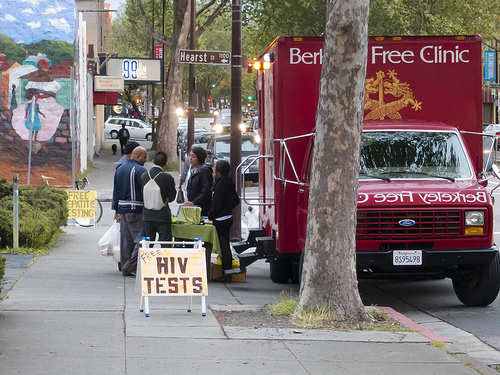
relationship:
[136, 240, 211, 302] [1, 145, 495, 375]
hiv test sign on sidewalk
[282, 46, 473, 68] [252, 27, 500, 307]
berkeley free clinic on truck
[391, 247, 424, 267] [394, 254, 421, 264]
license plate has blue numbers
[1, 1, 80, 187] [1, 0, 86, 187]
mural on wall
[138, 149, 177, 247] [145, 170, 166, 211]
man wearing backpack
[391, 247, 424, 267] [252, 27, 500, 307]
license plate on truck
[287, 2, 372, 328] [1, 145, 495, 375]
tree on sidewalk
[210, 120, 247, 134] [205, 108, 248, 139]
headlights on car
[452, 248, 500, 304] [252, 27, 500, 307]
tire on truck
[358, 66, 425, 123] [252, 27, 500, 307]
dragons on truck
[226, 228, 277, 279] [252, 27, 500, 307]
steps to truck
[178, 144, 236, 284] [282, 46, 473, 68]
employees of berkeley free clinic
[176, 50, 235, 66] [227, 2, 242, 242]
street sign on pole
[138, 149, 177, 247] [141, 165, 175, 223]
man wearing sweater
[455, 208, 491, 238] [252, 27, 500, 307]
lights on truck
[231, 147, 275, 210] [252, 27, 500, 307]
support rails on truck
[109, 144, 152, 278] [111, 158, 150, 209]
man wearing sweater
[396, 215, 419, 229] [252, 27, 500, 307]
ford logo on truck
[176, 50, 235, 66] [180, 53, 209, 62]
street sign says hearst